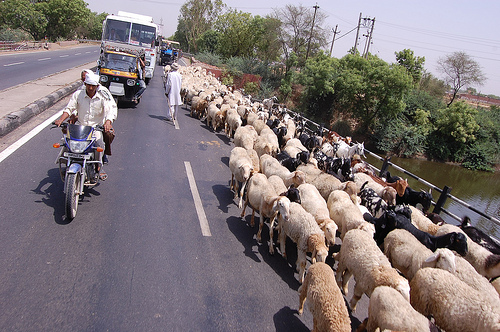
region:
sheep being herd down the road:
[187, 66, 469, 320]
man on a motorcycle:
[55, 60, 125, 226]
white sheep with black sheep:
[219, 133, 439, 316]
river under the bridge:
[384, 117, 495, 211]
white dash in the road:
[175, 135, 213, 254]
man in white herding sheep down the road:
[162, 55, 184, 130]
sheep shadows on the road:
[206, 162, 259, 286]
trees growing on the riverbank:
[305, 51, 492, 161]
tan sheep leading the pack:
[283, 254, 355, 325]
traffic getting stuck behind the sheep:
[99, 9, 164, 111]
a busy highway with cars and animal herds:
[11, 12, 480, 312]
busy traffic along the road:
[15, 18, 205, 198]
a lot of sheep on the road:
[175, 55, 482, 325]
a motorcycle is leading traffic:
[46, 81, 136, 224]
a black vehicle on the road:
[95, 46, 155, 111]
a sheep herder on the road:
[156, 57, 204, 132]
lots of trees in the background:
[263, 18, 491, 181]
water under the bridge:
[331, 115, 496, 245]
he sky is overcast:
[83, 0, 498, 99]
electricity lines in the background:
[303, 5, 496, 86]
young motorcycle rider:
[59, 63, 118, 235]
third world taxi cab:
[91, 39, 149, 104]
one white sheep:
[248, 171, 291, 247]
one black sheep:
[378, 203, 470, 264]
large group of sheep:
[159, 60, 499, 329]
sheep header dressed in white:
[161, 57, 186, 124]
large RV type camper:
[99, 5, 159, 85]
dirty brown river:
[313, 118, 498, 235]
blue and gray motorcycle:
[48, 116, 112, 221]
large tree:
[196, 8, 294, 73]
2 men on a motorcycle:
[62, 62, 114, 223]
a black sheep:
[390, 200, 472, 267]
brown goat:
[362, 159, 427, 206]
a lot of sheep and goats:
[198, 66, 420, 330]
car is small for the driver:
[92, 47, 148, 105]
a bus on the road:
[96, 0, 175, 90]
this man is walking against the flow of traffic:
[163, 65, 190, 123]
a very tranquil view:
[215, 20, 498, 155]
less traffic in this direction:
[12, 20, 54, 82]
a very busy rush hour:
[67, 11, 324, 330]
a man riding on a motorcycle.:
[29, 65, 126, 224]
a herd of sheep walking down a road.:
[157, 45, 498, 327]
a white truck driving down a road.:
[86, 11, 160, 111]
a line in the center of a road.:
[174, 151, 218, 256]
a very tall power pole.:
[349, 8, 382, 73]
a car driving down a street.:
[92, 45, 144, 112]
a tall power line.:
[298, 0, 325, 77]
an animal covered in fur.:
[286, 253, 363, 328]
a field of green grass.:
[0, 0, 105, 42]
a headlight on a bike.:
[66, 136, 91, 157]